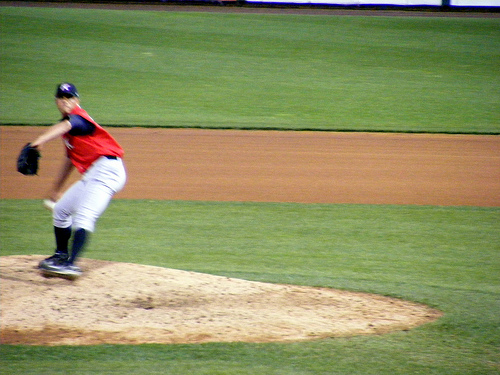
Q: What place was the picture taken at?
A: It was taken at the field.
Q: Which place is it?
A: It is a field.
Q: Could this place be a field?
A: Yes, it is a field.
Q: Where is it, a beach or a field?
A: It is a field.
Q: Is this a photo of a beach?
A: No, the picture is showing a field.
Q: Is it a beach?
A: No, it is a field.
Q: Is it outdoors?
A: Yes, it is outdoors.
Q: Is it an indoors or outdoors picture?
A: It is outdoors.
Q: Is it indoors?
A: No, it is outdoors.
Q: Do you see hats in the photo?
A: Yes, there is a hat.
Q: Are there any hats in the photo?
A: Yes, there is a hat.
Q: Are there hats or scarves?
A: Yes, there is a hat.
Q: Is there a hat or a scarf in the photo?
A: Yes, there is a hat.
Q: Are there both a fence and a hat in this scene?
A: No, there is a hat but no fences.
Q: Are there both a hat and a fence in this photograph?
A: No, there is a hat but no fences.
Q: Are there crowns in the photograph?
A: No, there are no crowns.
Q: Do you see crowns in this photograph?
A: No, there are no crowns.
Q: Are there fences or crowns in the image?
A: No, there are no crowns or fences.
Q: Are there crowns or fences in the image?
A: No, there are no crowns or fences.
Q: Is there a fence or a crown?
A: No, there are no crowns or fences.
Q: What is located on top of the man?
A: The hat is on top of the man.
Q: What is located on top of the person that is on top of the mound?
A: The hat is on top of the man.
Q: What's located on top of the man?
A: The hat is on top of the man.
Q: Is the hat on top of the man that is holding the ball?
A: Yes, the hat is on top of the man.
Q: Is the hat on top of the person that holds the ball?
A: Yes, the hat is on top of the man.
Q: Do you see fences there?
A: No, there are no fences.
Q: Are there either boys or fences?
A: No, there are no fences or boys.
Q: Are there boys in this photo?
A: No, there are no boys.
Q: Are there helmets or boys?
A: No, there are no boys or helmets.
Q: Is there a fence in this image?
A: No, there are no fences.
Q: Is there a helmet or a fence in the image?
A: No, there are no fences or helmets.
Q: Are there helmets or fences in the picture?
A: No, there are no fences or helmets.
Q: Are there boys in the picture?
A: No, there are no boys.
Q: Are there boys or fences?
A: No, there are no boys or fences.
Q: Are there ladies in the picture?
A: No, there are no ladies.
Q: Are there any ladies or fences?
A: No, there are no ladies or fences.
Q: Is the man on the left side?
A: Yes, the man is on the left of the image.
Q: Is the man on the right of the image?
A: No, the man is on the left of the image.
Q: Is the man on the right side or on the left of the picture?
A: The man is on the left of the image.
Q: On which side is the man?
A: The man is on the left of the image.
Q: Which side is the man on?
A: The man is on the left of the image.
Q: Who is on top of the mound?
A: The man is on top of the mound.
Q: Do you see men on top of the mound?
A: Yes, there is a man on top of the mound.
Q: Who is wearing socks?
A: The man is wearing socks.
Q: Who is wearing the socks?
A: The man is wearing socks.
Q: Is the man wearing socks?
A: Yes, the man is wearing socks.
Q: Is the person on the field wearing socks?
A: Yes, the man is wearing socks.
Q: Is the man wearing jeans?
A: No, the man is wearing socks.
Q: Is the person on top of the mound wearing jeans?
A: No, the man is wearing socks.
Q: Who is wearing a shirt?
A: The man is wearing a shirt.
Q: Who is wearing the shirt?
A: The man is wearing a shirt.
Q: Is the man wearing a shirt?
A: Yes, the man is wearing a shirt.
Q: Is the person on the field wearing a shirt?
A: Yes, the man is wearing a shirt.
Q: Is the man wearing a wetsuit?
A: No, the man is wearing a shirt.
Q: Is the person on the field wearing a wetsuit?
A: No, the man is wearing a shirt.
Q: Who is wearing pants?
A: The man is wearing pants.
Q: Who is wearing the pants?
A: The man is wearing pants.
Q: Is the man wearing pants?
A: Yes, the man is wearing pants.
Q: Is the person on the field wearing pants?
A: Yes, the man is wearing pants.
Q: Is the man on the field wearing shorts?
A: No, the man is wearing pants.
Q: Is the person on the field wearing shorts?
A: No, the man is wearing pants.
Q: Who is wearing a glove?
A: The man is wearing a glove.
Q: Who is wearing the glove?
A: The man is wearing a glove.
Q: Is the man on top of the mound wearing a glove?
A: Yes, the man is wearing a glove.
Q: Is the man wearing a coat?
A: No, the man is wearing a glove.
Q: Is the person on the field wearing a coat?
A: No, the man is wearing a glove.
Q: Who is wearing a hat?
A: The man is wearing a hat.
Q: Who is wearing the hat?
A: The man is wearing a hat.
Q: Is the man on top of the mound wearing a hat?
A: Yes, the man is wearing a hat.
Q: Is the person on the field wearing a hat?
A: Yes, the man is wearing a hat.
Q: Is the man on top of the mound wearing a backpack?
A: No, the man is wearing a hat.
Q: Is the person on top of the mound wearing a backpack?
A: No, the man is wearing a hat.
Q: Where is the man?
A: The man is on the field.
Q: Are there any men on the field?
A: Yes, there is a man on the field.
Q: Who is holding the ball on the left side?
A: The man is holding the ball.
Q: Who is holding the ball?
A: The man is holding the ball.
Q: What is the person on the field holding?
A: The man is holding the ball.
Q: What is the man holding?
A: The man is holding the ball.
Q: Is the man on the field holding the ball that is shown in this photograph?
A: Yes, the man is holding the ball.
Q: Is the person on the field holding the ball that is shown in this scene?
A: Yes, the man is holding the ball.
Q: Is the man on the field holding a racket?
A: No, the man is holding the ball.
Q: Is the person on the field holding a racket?
A: No, the man is holding the ball.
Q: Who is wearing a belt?
A: The man is wearing a belt.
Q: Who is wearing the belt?
A: The man is wearing a belt.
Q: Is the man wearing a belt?
A: Yes, the man is wearing a belt.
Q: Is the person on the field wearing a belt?
A: Yes, the man is wearing a belt.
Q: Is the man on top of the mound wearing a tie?
A: No, the man is wearing a belt.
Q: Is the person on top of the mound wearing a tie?
A: No, the man is wearing a belt.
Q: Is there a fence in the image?
A: No, there are no fences.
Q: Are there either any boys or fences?
A: No, there are no fences or boys.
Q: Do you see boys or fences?
A: No, there are no fences or boys.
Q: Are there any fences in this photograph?
A: No, there are no fences.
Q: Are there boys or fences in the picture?
A: No, there are no fences or boys.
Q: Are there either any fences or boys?
A: No, there are no fences or boys.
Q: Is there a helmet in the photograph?
A: No, there are no helmets.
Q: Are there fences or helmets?
A: No, there are no helmets or fences.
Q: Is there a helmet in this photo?
A: No, there are no helmets.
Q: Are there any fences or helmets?
A: No, there are no helmets or fences.